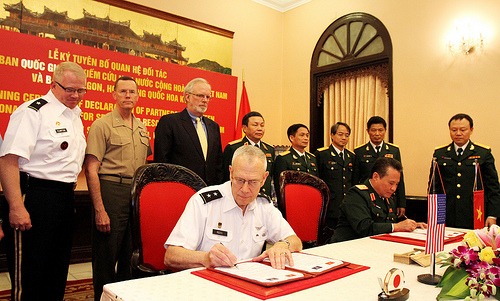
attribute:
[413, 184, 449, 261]
us flag — mini, american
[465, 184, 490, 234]
chinese flag — mini, red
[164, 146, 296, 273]
man — old, person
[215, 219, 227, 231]
patch — american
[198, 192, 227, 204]
patch — two stars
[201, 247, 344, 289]
papers — official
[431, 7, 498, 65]
light — bright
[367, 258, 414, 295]
ornament — glass, small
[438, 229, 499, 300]
flowers — vivid, beautiful, pink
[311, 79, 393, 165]
curtain — beige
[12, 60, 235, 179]
diplomats — american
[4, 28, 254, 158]
sign — red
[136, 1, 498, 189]
walls — beige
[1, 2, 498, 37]
ceiling — white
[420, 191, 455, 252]
flag — red, white, blue, miniature, us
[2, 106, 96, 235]
army uniform — white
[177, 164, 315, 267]
army uniform — white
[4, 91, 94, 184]
shirt — white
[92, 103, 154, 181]
shirt — tan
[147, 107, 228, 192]
jacket — black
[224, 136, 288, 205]
jacket — green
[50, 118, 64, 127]
patch — yellow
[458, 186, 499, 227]
flag — yellow, chinese, miniature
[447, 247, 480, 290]
flower — white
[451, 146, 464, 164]
tie — black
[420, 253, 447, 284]
stand — brow, small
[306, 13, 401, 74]
window — glass